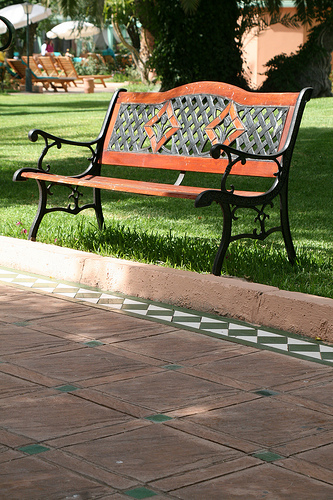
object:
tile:
[170, 312, 205, 329]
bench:
[13, 81, 316, 278]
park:
[0, 2, 330, 499]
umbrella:
[46, 20, 101, 40]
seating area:
[7, 54, 110, 102]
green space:
[11, 98, 95, 129]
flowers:
[115, 68, 126, 76]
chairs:
[8, 58, 76, 91]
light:
[47, 19, 126, 48]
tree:
[126, 3, 255, 91]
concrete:
[94, 86, 116, 92]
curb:
[2, 234, 331, 337]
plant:
[3, 71, 21, 90]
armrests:
[28, 130, 99, 177]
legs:
[274, 195, 297, 261]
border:
[0, 258, 332, 366]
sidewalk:
[0, 280, 328, 496]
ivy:
[217, 16, 238, 71]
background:
[8, 3, 134, 96]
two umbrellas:
[0, 3, 100, 41]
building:
[233, 6, 323, 92]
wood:
[108, 81, 305, 108]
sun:
[108, 25, 121, 49]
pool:
[95, 32, 124, 56]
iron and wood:
[266, 81, 313, 183]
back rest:
[94, 81, 295, 172]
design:
[141, 100, 182, 153]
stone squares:
[38, 362, 274, 481]